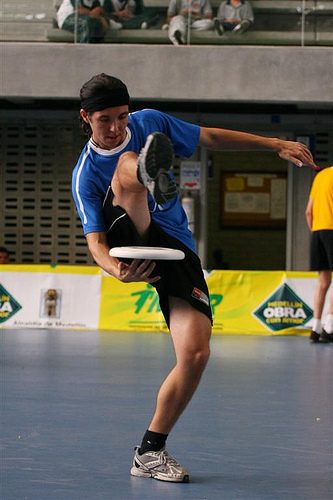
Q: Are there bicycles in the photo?
A: No, there are no bicycles.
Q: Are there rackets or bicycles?
A: No, there are no bicycles or rackets.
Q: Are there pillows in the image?
A: No, there are no pillows.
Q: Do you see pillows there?
A: No, there are no pillows.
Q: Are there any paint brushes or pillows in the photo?
A: No, there are no pillows or paint brushes.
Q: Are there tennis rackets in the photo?
A: No, there are no tennis rackets.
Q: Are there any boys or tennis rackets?
A: No, there are no tennis rackets or boys.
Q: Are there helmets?
A: No, there are no helmets.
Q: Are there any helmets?
A: No, there are no helmets.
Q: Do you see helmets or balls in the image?
A: No, there are no helmets or balls.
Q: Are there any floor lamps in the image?
A: No, there are no floor lamps.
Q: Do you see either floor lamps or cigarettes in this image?
A: No, there are no floor lamps or cigarettes.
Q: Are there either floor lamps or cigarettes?
A: No, there are no floor lamps or cigarettes.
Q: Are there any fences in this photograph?
A: No, there are no fences.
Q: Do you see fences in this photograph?
A: No, there are no fences.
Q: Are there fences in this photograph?
A: No, there are no fences.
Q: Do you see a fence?
A: No, there are no fences.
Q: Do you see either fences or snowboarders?
A: No, there are no fences or snowboarders.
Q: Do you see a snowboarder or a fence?
A: No, there are no fences or snowboarders.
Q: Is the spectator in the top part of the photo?
A: Yes, the spectator is in the top of the image.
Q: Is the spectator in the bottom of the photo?
A: No, the spectator is in the top of the image.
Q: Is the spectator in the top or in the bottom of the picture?
A: The spectator is in the top of the image.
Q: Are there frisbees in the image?
A: Yes, there is a frisbee.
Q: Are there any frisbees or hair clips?
A: Yes, there is a frisbee.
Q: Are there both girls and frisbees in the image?
A: No, there is a frisbee but no girls.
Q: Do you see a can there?
A: No, there are no cans.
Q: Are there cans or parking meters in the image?
A: No, there are no cans or parking meters.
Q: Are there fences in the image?
A: No, there are no fences.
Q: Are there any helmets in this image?
A: No, there are no helmets.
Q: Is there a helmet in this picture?
A: No, there are no helmets.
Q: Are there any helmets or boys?
A: No, there are no helmets or boys.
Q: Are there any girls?
A: No, there are no girls.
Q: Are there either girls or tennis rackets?
A: No, there are no girls or tennis rackets.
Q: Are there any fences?
A: No, there are no fences.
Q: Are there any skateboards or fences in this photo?
A: No, there are no fences or skateboards.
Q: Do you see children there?
A: No, there are no children.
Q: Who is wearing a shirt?
A: The man is wearing a shirt.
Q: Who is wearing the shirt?
A: The man is wearing a shirt.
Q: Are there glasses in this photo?
A: No, there are no glasses.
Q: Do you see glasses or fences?
A: No, there are no glasses or fences.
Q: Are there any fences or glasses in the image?
A: No, there are no glasses or fences.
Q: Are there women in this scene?
A: No, there are no women.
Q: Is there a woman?
A: No, there are no women.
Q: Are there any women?
A: No, there are no women.